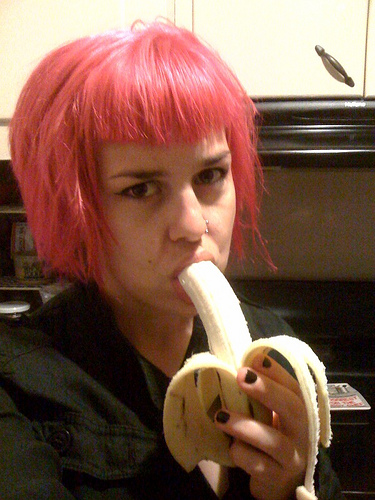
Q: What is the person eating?
A: A banana.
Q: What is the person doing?
A: Eating a banana.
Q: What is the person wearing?
A: A green top.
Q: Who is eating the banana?
A: A person with weird pink hair.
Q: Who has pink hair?
A: The girl.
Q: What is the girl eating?
A: A banana.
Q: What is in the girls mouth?
A: A banana.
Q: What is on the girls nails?
A: Black nail polish.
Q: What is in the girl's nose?
A: A piercing.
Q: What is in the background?
A: Cabinets.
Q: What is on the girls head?
A: Pink hair.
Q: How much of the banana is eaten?
A: Half.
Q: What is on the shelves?
A: Food.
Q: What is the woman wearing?
A: A black shirt.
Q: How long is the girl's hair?
A: Short.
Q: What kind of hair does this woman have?
A: Pink.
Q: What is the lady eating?
A: Banana.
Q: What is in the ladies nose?
A: Piercings.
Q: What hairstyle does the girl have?
A: Short.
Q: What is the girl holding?
A: A banana.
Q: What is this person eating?
A: Banana.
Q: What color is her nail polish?
A: Black.